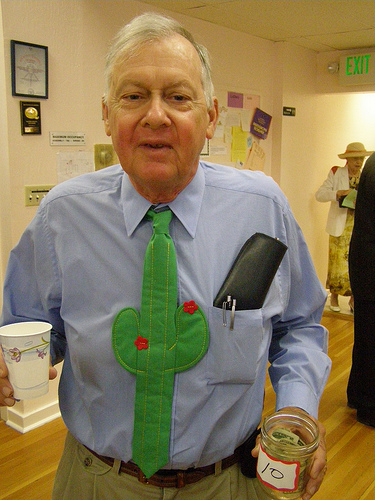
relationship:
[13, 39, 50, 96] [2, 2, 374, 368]
plaque on wall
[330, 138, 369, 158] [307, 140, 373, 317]
hat on woman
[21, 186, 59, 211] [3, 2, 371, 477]
panel on wall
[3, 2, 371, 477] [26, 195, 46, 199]
wall with buttons